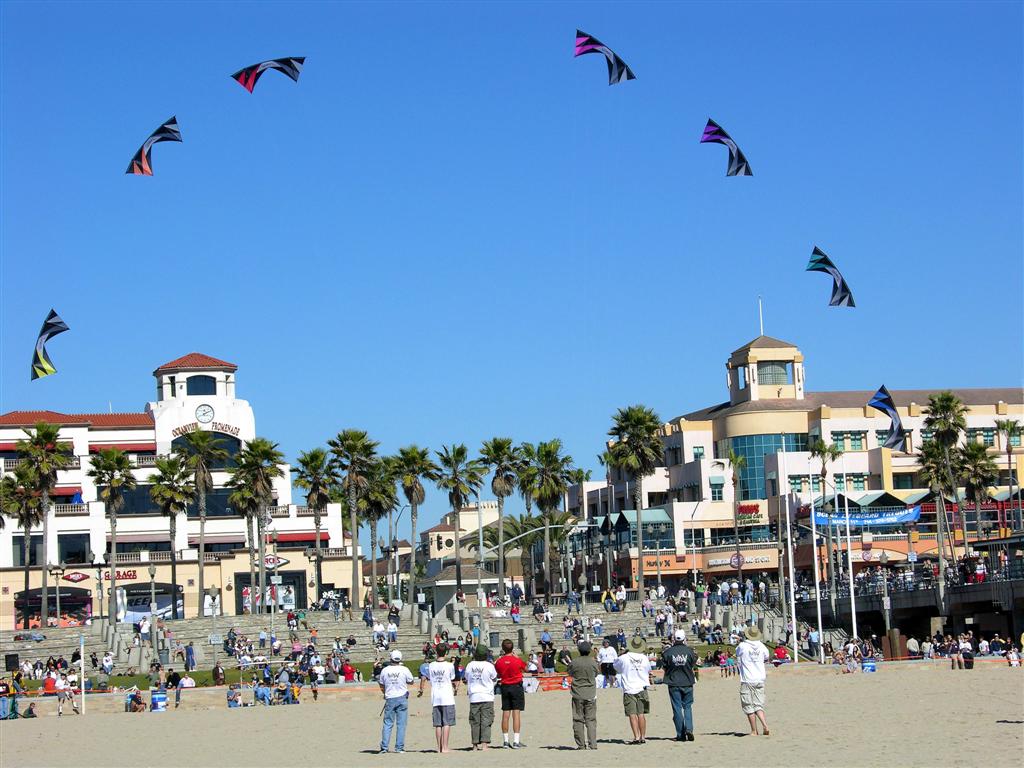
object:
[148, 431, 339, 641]
palm tree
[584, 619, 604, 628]
pants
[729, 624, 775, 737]
person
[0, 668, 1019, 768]
beach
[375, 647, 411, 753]
person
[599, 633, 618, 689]
person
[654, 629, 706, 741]
person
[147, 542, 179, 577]
window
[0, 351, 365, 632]
building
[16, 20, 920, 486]
show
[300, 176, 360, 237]
kite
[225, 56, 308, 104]
kite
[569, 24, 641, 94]
kite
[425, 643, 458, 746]
person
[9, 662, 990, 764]
beach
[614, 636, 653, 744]
human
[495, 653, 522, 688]
shirt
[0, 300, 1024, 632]
stadium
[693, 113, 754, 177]
kite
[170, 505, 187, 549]
wall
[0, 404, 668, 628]
trees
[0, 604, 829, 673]
sidewalk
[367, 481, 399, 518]
leaves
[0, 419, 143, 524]
leaves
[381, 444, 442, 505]
leaves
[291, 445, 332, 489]
leaves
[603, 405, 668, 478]
leaves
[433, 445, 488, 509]
leaves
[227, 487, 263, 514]
leaves